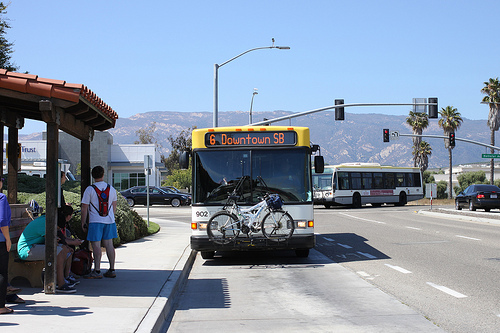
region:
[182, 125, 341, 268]
One large city bus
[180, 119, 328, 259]
One large city bus with yellow trim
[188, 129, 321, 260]
One large city bus with bike in front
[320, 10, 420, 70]
Clear blue sunny day no white clouds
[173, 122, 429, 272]
Two city buses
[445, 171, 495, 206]
Black car waiting at stop light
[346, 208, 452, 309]
Gray street with white stripes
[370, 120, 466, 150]
Two stop lights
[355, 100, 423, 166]
Mountain and hills on background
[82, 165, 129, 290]
Person standing have white t shirt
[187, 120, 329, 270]
a bus on the street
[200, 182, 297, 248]
a bicycle on the front of the bus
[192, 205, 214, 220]
the bus number is 902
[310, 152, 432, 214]
a bus making a turn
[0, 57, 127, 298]
a shelter on the sidewalk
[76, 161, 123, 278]
a man on the sidewalk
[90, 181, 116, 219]
a pack on his back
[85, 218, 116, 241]
his shorts are blue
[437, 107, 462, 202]
a palm tree by the street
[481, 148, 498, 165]
a sign on the traffic signal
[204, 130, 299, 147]
A bus display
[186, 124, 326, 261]
A yellow and white bus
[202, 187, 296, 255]
A bicycle on the front of the bus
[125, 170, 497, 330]
The road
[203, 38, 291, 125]
Streetlights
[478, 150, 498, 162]
A green and white street sign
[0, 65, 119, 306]
A bus stop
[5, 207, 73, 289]
A bench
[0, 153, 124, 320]
People waiting at a bus stop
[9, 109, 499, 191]
A mountain range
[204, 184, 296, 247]
Bicycle on front of bus.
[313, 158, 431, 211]
Bus turning into street.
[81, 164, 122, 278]
Person with backpack standing at bus stop.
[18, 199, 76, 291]
People sitting at the bus stop.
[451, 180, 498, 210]
Car stopped at traffic light.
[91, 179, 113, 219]
Small backpack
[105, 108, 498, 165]
Mountains in the distance.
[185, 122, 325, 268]
Bus heading downtown.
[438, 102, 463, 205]
Palm tree on side of road.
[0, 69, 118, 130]
Roof over bus stop